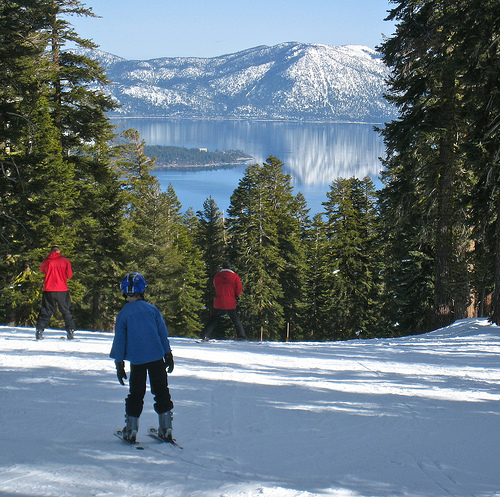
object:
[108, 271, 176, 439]
child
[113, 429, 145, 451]
ski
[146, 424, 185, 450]
ski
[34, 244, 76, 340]
person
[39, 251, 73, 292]
jacket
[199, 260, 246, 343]
person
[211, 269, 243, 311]
jacket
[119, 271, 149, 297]
helmet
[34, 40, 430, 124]
mountain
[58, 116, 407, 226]
lake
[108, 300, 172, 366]
jacket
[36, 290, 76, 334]
pants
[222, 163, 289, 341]
tree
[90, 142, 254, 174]
islet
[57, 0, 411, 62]
sky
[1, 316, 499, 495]
ground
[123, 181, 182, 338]
tree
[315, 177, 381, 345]
tree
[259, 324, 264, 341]
trunk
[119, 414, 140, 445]
boot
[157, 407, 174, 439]
boot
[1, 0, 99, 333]
tree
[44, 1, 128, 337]
tree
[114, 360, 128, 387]
glove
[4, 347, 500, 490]
shadow